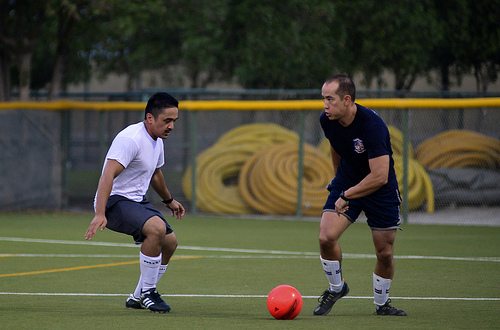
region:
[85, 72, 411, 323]
Two people playing soccer.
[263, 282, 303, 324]
An orange soccer ball.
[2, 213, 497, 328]
A green soccer field.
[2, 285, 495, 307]
White stripe on a soccer field.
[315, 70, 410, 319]
Man playing soccer.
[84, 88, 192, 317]
Man wearing a white t-shirt.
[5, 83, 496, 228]
Green fence behind two men playing soccer.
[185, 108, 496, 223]
Yellow coiled objects behind a fence.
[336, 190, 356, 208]
Watch of a man playing soccer.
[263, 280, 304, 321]
Ball in a soccer field.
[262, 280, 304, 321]
red soccer ball on green field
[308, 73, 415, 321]
bald man getting ready to kick soccer ball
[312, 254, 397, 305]
man wearing white shin guards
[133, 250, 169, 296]
man wearing white shin guards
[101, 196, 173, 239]
man wearing navy blue shorts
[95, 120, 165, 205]
HBispanic looking man wearing white shirt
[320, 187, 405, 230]
bald man wearing blue shorts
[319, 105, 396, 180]
bald man wearing blue federation tee shirt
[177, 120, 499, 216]
large coils of yellow piping behind fence in background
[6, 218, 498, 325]
green soccer field with white and yellow chalk lines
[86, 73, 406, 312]
two men playing soccer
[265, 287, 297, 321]
a red soccer ball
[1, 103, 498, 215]
a green fence with a yellow top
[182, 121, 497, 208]
rolls of yellow plastic hose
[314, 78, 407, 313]
player with the dark blue shirt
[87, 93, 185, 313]
player with the white shirt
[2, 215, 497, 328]
artificial turf field with lines on it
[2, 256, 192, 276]
one yellow line on the field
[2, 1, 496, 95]
tree tops behind the fence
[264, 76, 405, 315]
man in dark blue kicking the soccer ball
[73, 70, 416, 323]
Two men playing soccer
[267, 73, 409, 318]
soccer player readying to the kick the ball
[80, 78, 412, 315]
two soccer players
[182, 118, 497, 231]
pile of yellow hoses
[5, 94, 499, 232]
green fencing with yellow stripe at the top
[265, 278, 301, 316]
red soccer ball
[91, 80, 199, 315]
soccer player wearing white shirt and gray shorts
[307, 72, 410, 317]
soccer player wearing navy uniform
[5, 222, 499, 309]
white lines painted on the field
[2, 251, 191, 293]
yellow lines painted on the field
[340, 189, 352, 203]
black wristwatch on man in navy blue's wrist